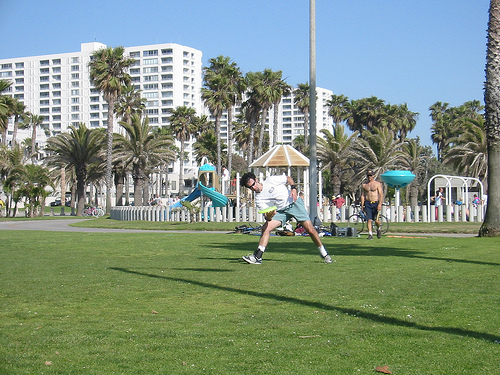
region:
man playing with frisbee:
[233, 170, 335, 266]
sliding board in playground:
[168, 157, 230, 213]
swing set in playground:
[426, 173, 483, 217]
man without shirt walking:
[356, 169, 385, 245]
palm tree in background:
[43, 125, 105, 219]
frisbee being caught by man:
[258, 205, 276, 215]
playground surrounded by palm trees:
[110, 163, 488, 225]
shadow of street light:
[108, 263, 498, 357]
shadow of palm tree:
[205, 238, 499, 270]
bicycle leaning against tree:
[80, 203, 105, 225]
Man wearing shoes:
[237, 249, 337, 267]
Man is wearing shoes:
[237, 250, 340, 265]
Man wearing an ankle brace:
[251, 244, 264, 260]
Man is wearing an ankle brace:
[251, 242, 267, 262]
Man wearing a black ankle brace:
[252, 242, 266, 260]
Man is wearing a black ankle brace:
[247, 240, 266, 260]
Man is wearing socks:
[255, 237, 331, 258]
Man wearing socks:
[247, 241, 334, 261]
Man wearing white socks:
[255, 239, 334, 257]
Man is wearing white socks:
[255, 240, 328, 257]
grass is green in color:
[57, 268, 324, 347]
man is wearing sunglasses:
[240, 178, 262, 190]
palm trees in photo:
[83, 52, 147, 202]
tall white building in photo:
[18, 47, 202, 107]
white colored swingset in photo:
[426, 171, 485, 204]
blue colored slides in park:
[182, 156, 232, 206]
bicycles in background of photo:
[73, 200, 110, 220]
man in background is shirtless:
[357, 167, 385, 230]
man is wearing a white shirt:
[256, 176, 299, 212]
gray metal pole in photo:
[305, 4, 322, 219]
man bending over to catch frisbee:
[224, 150, 332, 273]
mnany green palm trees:
[11, 69, 466, 211]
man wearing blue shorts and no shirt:
[353, 165, 397, 237]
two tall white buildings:
[2, 20, 341, 195]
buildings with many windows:
[6, 47, 341, 189]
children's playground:
[170, 139, 487, 231]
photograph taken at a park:
[12, 6, 469, 364]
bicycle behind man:
[350, 194, 398, 231]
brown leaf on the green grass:
[371, 356, 399, 371]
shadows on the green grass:
[107, 221, 488, 366]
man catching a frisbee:
[238, 170, 330, 272]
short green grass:
[131, 278, 296, 332]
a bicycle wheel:
[348, 213, 365, 235]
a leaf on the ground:
[374, 365, 392, 373]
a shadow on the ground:
[239, 278, 387, 358]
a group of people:
[426, 181, 488, 208]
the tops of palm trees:
[201, 58, 286, 117]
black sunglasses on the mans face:
[246, 177, 259, 193]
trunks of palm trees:
[57, 175, 89, 213]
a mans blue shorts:
[363, 204, 382, 223]